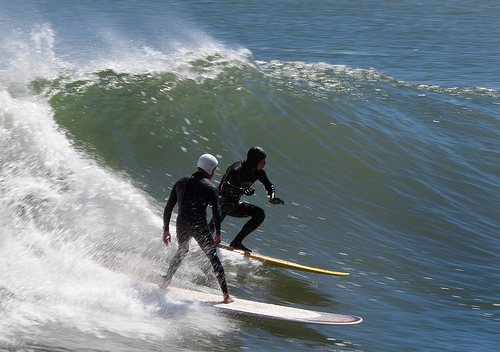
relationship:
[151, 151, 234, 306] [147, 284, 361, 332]
man on surfboard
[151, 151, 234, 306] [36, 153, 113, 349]
man riding wave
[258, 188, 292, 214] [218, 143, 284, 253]
hand on man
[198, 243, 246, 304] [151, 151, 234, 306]
leg on man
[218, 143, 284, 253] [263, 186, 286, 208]
man wearing glove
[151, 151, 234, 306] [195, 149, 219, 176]
man wearing cap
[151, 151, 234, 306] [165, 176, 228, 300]
man wearing black